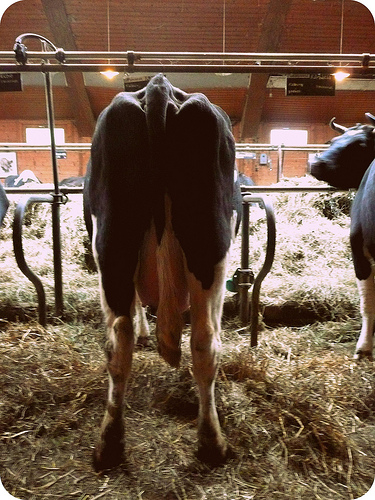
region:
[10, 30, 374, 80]
Poles above the cows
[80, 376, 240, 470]
Cow's two back feet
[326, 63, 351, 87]
Bright yellow light suspended in the air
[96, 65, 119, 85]
Bright yellow light suspended in the air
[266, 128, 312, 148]
Bright window on the back wall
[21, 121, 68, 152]
Bright window on the back wall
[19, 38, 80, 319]
Tall metal pole next to cow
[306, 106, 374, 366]
Cow looking towards the camera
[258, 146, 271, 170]
Metal box adhered to the back wall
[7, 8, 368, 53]
Wooden ceiling of the building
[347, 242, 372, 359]
white and black leg of cow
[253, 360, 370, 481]
hay or straw in a cow barn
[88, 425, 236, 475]
cow's two back hooves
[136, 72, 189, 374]
a cow's black and white tail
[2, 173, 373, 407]
cows in a cow barn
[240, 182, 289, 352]
metal rail in a cow barn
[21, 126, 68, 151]
window in cow barn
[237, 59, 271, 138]
rafter in a cow barn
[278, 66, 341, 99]
sign in a cow barn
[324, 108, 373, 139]
curved horns on a cow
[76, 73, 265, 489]
a black cow with white legs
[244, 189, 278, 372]
a curved metal bar between cows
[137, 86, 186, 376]
a black and white tail of cow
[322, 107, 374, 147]
two horns on bull's head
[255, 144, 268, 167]
an electrical box on wall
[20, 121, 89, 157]
a window on the left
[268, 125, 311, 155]
a window on the right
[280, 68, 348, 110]
a black sign with white writting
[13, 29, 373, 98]
a bar above the cows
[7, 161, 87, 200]
tops of cows backs on other side of room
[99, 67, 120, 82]
The light is on.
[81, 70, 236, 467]
The cow is black and white.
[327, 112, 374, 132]
The cow has horns.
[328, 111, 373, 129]
The horns are gray.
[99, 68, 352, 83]
A row of lights.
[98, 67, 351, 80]
The lights are on.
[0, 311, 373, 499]
Hay is on the ground.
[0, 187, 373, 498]
The hay is brown.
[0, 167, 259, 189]
Cows are in the background.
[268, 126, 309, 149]
A window is in the background.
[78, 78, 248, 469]
the backside of a cow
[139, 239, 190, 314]
back of a cow's udder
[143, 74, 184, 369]
the tail of a cow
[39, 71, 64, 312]
a metal post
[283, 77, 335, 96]
a black and white sign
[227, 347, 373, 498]
hay on the ground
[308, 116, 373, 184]
the head of a cow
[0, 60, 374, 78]
a long metal beam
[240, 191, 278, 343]
a curved metal pole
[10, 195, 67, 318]
a curved metal pole